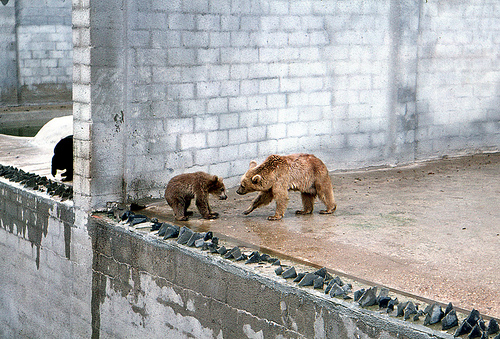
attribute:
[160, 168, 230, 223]
small bear — brown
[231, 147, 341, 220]
big bear — brown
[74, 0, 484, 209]
wall — gray, stone